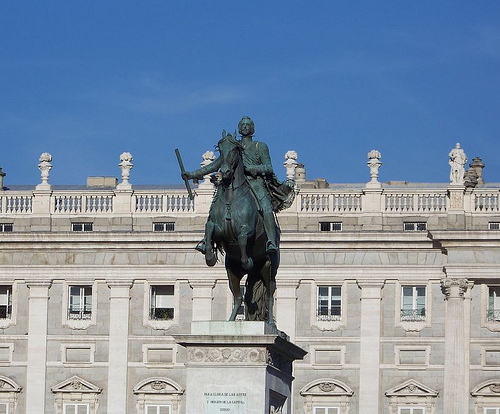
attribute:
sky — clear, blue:
[0, 0, 498, 190]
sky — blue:
[7, 7, 488, 108]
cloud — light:
[167, 72, 257, 109]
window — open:
[64, 280, 98, 318]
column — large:
[341, 129, 395, 411]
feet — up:
[199, 245, 220, 265]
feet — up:
[238, 253, 254, 269]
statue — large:
[174, 115, 294, 323]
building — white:
[11, 168, 490, 411]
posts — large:
[18, 134, 487, 185]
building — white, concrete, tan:
[0, 140, 498, 410]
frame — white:
[307, 280, 348, 329]